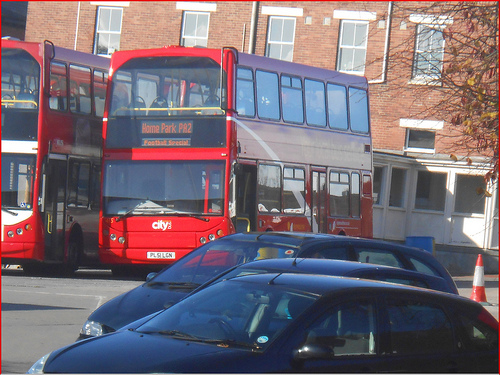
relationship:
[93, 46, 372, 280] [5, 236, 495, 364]
bus parked in lot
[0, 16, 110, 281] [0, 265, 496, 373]
bus parked in lot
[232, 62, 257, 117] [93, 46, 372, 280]
window on bus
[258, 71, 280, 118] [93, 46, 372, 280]
window on bus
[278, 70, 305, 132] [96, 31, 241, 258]
window on a bus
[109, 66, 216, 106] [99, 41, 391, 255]
window on a bus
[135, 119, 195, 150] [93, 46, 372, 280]
sign on a bus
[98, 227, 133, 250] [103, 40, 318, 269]
lights on a bus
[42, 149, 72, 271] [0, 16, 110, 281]
door on bus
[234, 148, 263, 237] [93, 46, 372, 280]
door on bus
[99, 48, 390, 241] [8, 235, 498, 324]
bus on a street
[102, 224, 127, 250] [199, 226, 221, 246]
headlight on a headlight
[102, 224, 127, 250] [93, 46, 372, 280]
headlight on a bus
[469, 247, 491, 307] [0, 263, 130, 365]
cone on street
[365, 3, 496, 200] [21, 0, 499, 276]
tree near building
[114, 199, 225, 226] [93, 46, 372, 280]
windshield wiper on bus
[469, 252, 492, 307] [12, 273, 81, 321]
cone in street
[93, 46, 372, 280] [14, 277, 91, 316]
bus in street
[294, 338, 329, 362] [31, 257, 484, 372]
sideview mirrow on car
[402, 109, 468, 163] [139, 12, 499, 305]
window on building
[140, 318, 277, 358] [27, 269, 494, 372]
wipers on car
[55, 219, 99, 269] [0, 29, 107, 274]
tires on bus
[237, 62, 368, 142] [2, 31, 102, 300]
windows on bus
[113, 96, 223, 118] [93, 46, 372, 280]
rail in bus